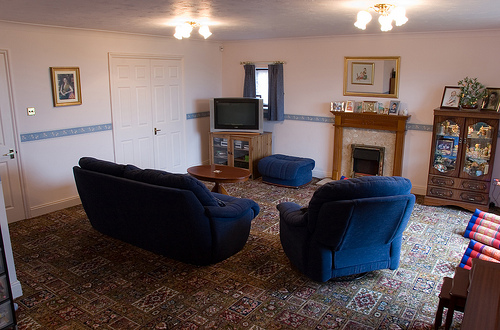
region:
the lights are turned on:
[346, 0, 418, 35]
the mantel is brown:
[336, 105, 396, 129]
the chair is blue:
[328, 202, 381, 223]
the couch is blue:
[121, 170, 172, 220]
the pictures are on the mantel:
[331, 100, 416, 122]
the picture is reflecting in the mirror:
[341, 48, 398, 97]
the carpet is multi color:
[250, 290, 303, 311]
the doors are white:
[136, 90, 179, 123]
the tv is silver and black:
[209, 95, 246, 122]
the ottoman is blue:
[268, 155, 295, 178]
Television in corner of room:
[195, 85, 275, 135]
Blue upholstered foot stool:
[256, 148, 315, 188]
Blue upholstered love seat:
[68, 151, 263, 274]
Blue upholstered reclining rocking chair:
[268, 172, 417, 285]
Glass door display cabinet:
[423, 102, 498, 209]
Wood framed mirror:
[340, 50, 405, 100]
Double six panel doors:
[105, 49, 190, 180]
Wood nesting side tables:
[426, 252, 498, 320]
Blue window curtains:
[238, 55, 292, 122]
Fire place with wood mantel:
[323, 105, 409, 192]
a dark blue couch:
[69, 151, 256, 266]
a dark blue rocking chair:
[273, 173, 415, 284]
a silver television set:
[206, 98, 266, 133]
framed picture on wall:
[45, 63, 85, 110]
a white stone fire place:
[340, 126, 394, 178]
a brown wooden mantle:
[326, 107, 412, 136]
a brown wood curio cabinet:
[424, 105, 499, 214]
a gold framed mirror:
[341, 54, 399, 98]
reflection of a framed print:
[349, 60, 376, 87]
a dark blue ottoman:
[252, 149, 313, 189]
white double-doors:
[107, 50, 187, 168]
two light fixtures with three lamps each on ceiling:
[152, 0, 419, 40]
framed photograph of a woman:
[46, 60, 86, 110]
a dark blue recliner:
[276, 173, 417, 283]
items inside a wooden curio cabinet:
[424, 108, 499, 214]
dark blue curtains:
[235, 57, 283, 123]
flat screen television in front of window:
[208, 63, 285, 133]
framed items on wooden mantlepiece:
[329, 98, 407, 178]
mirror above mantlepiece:
[331, 50, 409, 177]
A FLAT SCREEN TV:
[204, 89, 266, 139]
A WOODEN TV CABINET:
[199, 126, 278, 176]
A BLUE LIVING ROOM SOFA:
[66, 151, 264, 272]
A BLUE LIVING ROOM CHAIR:
[274, 167, 416, 287]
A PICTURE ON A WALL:
[45, 60, 88, 110]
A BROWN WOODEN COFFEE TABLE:
[181, 156, 261, 198]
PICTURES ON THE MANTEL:
[326, 96, 412, 121]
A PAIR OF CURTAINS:
[236, 55, 293, 126]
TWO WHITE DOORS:
[99, 49, 208, 176]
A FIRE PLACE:
[331, 116, 402, 188]